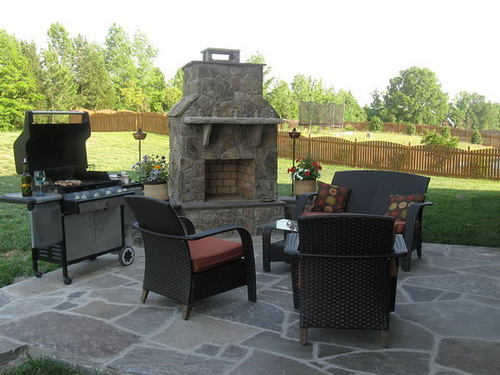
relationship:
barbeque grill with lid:
[5, 110, 142, 285] [12, 110, 89, 174]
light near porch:
[287, 129, 299, 188] [1, 226, 500, 371]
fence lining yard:
[69, 107, 500, 180] [1, 129, 498, 283]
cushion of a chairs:
[185, 237, 244, 268] [121, 193, 258, 319]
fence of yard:
[278, 137, 483, 176] [0, 122, 185, 182]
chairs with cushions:
[111, 164, 436, 343] [175, 229, 251, 259]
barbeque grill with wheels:
[0, 110, 146, 284] [115, 240, 138, 270]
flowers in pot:
[285, 156, 325, 180] [290, 177, 319, 196]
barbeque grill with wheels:
[0, 110, 146, 284] [26, 244, 138, 285]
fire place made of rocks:
[168, 47, 287, 233] [196, 63, 257, 113]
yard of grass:
[4, 124, 484, 251] [99, 133, 128, 156]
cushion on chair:
[187, 235, 242, 271] [120, 190, 261, 320]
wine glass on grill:
[33, 168, 49, 193] [8, 106, 129, 283]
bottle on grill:
[17, 155, 32, 197] [8, 106, 129, 283]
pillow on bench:
[315, 179, 350, 214] [320, 167, 430, 218]